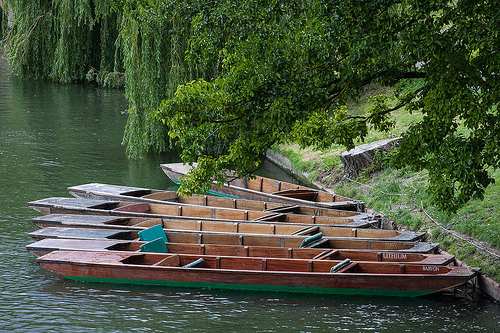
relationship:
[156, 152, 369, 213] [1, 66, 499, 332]
boats in water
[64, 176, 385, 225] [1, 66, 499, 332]
boats in water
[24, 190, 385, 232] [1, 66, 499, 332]
boats in water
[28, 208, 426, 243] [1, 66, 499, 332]
boats in water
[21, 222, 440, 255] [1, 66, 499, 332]
boats in water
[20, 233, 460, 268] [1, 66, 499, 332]
boats in water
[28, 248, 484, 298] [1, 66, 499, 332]
boats in water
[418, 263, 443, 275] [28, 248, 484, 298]
letters on boats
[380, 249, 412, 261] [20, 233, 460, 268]
letters on boats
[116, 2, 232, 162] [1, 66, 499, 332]
tree in water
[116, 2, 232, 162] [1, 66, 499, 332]
tree over water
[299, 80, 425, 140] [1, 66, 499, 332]
limbs over water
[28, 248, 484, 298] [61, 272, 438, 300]
boats has stripe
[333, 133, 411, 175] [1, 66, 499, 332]
stump by water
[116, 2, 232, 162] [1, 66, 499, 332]
tree on water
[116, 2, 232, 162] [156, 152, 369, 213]
tree over boats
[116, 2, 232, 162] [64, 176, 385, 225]
tree over boats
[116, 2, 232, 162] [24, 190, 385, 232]
tree over boats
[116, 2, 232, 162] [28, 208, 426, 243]
tree over boats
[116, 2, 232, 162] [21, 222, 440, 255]
tree over boats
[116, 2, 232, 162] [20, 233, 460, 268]
tree over boats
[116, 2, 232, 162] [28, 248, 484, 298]
tree over boats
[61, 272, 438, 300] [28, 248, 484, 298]
stripe on boats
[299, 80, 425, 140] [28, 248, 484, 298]
limbs over boats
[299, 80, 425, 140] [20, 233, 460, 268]
limbs over boats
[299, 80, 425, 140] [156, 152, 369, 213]
limbs over boats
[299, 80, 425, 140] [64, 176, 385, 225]
limbs over boats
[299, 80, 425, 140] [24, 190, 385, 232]
limbs over boats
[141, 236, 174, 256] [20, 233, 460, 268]
seats in boats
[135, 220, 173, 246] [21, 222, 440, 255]
seats in boats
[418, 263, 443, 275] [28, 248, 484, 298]
letters in boats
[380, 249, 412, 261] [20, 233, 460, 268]
letters in boats